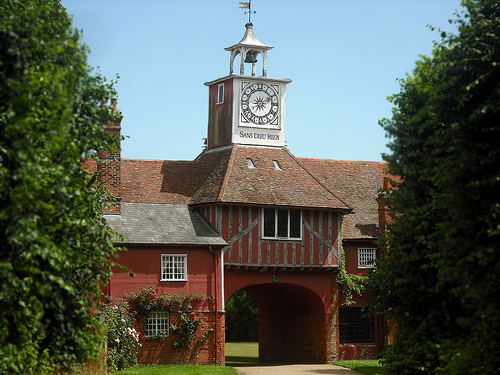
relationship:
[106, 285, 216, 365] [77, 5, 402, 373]
climbing rose climbing building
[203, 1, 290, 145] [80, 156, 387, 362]
clock tower on building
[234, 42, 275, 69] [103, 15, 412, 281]
bell in tower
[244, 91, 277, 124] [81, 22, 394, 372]
face on tower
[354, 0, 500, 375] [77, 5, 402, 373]
hedge growing building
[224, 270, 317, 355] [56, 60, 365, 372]
tunnel of building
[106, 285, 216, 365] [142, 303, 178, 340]
climbing rose growing window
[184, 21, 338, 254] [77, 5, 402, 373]
tower on building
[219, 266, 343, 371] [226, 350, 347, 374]
archway over pathway